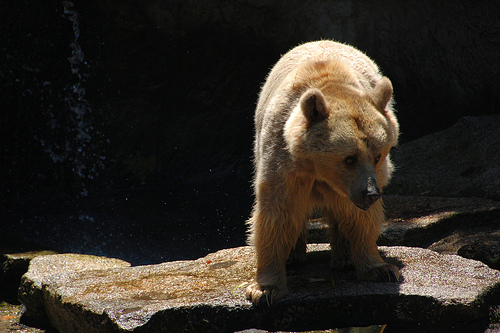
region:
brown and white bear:
[251, 40, 393, 285]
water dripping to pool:
[35, 16, 95, 231]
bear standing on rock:
[245, 31, 390, 286]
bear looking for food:
[255, 40, 385, 275]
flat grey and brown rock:
[30, 251, 497, 327]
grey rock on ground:
[25, 246, 495, 317]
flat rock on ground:
[255, 115, 495, 230]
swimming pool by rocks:
[7, 190, 261, 262]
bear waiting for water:
[250, 38, 400, 288]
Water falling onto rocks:
[45, 8, 121, 246]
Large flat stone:
[22, 248, 499, 330]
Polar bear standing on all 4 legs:
[241, 35, 415, 307]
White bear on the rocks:
[213, 34, 462, 326]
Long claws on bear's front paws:
[244, 262, 412, 308]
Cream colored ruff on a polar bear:
[305, 57, 378, 114]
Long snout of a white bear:
[332, 138, 391, 213]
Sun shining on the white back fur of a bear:
[248, 38, 402, 213]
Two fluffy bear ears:
[298, 78, 400, 125]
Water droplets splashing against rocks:
[41, 189, 239, 246]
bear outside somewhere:
[258, 38, 424, 230]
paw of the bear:
[238, 254, 293, 316]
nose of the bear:
[348, 179, 383, 213]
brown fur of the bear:
[277, 33, 357, 120]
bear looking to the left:
[307, 73, 426, 210]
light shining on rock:
[168, 235, 235, 302]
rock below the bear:
[140, 257, 203, 314]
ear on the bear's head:
[291, 83, 338, 128]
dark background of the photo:
[99, 38, 199, 113]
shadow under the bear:
[203, 241, 469, 321]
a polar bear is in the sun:
[241, 35, 402, 305]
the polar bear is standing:
[240, 35, 402, 303]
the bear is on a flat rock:
[21, 238, 492, 331]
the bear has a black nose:
[357, 180, 378, 202]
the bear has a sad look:
[325, 140, 391, 207]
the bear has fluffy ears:
[293, 75, 394, 125]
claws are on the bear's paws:
[256, 262, 406, 307]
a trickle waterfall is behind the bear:
[30, 10, 250, 257]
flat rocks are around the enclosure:
[10, 107, 498, 327]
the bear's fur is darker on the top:
[278, 54, 402, 210]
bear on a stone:
[192, 87, 400, 309]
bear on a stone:
[132, 42, 404, 290]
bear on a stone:
[211, 87, 396, 300]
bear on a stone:
[231, 103, 402, 298]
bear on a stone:
[247, 35, 457, 313]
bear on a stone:
[264, 30, 395, 267]